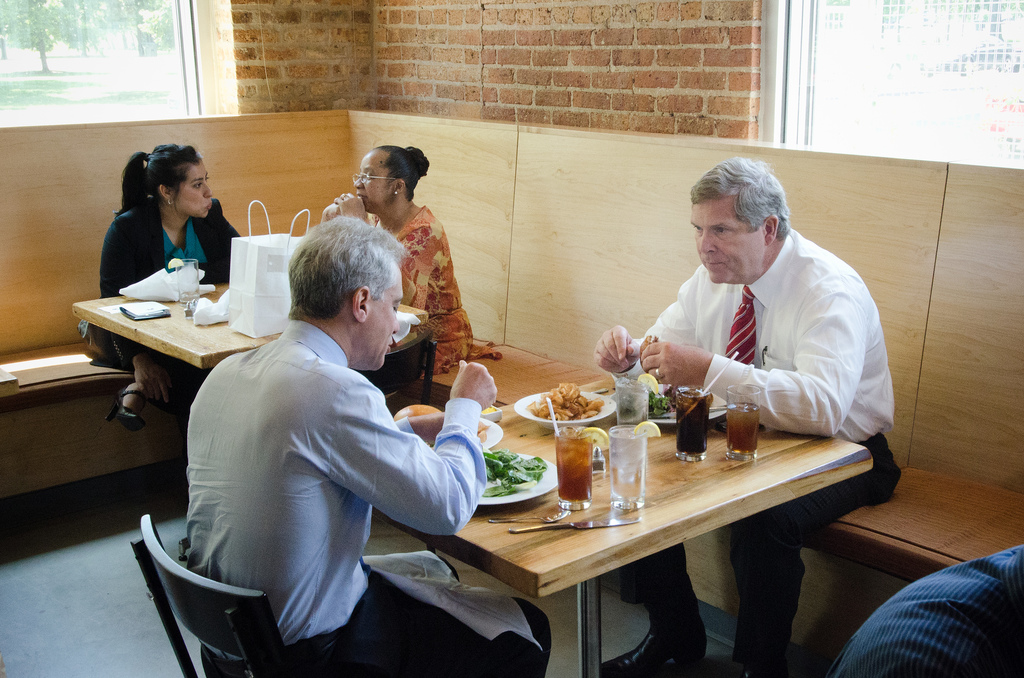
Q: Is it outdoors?
A: Yes, it is outdoors.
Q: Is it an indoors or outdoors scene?
A: It is outdoors.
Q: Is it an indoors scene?
A: No, it is outdoors.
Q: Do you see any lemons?
A: Yes, there is a lemon.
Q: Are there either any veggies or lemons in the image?
A: Yes, there is a lemon.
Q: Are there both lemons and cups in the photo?
A: Yes, there are both a lemon and a cup.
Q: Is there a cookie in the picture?
A: No, there are no cookies.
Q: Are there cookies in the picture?
A: No, there are no cookies.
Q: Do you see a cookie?
A: No, there are no cookies.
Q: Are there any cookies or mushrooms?
A: No, there are no cookies or mushrooms.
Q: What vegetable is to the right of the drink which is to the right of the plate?
A: The vegetable is a lemon.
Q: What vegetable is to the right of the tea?
A: The vegetable is a lemon.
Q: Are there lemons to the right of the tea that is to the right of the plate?
A: Yes, there is a lemon to the right of the tea.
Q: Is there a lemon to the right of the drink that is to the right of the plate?
A: Yes, there is a lemon to the right of the tea.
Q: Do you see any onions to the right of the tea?
A: No, there is a lemon to the right of the tea.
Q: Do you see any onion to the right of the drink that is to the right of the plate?
A: No, there is a lemon to the right of the tea.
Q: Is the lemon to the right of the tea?
A: Yes, the lemon is to the right of the tea.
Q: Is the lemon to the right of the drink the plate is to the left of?
A: Yes, the lemon is to the right of the tea.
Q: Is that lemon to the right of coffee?
A: No, the lemon is to the right of the tea.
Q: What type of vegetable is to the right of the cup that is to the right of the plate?
A: The vegetable is a lemon.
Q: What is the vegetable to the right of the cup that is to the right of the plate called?
A: The vegetable is a lemon.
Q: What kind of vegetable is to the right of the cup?
A: The vegetable is a lemon.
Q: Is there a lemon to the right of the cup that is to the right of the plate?
A: Yes, there is a lemon to the right of the cup.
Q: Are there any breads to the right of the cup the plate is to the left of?
A: No, there is a lemon to the right of the cup.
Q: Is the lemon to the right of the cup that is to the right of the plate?
A: Yes, the lemon is to the right of the cup.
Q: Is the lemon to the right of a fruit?
A: No, the lemon is to the right of the cup.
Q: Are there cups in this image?
A: Yes, there is a cup.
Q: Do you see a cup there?
A: Yes, there is a cup.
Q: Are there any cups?
A: Yes, there is a cup.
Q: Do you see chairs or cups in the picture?
A: Yes, there is a cup.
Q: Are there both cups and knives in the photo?
A: Yes, there are both a cup and a knife.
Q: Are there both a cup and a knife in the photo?
A: Yes, there are both a cup and a knife.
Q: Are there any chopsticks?
A: No, there are no chopsticks.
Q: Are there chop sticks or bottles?
A: No, there are no chop sticks or bottles.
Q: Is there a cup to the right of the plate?
A: Yes, there is a cup to the right of the plate.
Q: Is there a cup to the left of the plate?
A: No, the cup is to the right of the plate.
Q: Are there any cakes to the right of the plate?
A: No, there is a cup to the right of the plate.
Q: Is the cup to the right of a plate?
A: Yes, the cup is to the right of a plate.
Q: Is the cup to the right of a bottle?
A: No, the cup is to the right of a plate.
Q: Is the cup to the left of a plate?
A: No, the cup is to the right of a plate.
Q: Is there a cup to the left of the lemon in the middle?
A: Yes, there is a cup to the left of the lemon.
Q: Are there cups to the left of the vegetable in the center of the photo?
A: Yes, there is a cup to the left of the lemon.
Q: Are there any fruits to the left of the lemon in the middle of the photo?
A: No, there is a cup to the left of the lemon.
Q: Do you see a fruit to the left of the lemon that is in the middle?
A: No, there is a cup to the left of the lemon.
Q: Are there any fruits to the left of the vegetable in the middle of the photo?
A: No, there is a cup to the left of the lemon.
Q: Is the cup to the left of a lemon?
A: Yes, the cup is to the left of a lemon.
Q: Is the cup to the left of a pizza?
A: No, the cup is to the left of a lemon.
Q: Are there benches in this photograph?
A: Yes, there is a bench.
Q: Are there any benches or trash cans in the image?
A: Yes, there is a bench.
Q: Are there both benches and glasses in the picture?
A: Yes, there are both a bench and glasses.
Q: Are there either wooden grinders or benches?
A: Yes, there is a wood bench.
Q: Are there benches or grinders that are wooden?
A: Yes, the bench is wooden.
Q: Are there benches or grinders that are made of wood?
A: Yes, the bench is made of wood.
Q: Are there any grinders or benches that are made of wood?
A: Yes, the bench is made of wood.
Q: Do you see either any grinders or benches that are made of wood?
A: Yes, the bench is made of wood.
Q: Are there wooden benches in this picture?
A: Yes, there is a wood bench.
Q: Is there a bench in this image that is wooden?
A: Yes, there is a bench that is wooden.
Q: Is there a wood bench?
A: Yes, there is a bench that is made of wood.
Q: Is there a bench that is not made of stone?
A: Yes, there is a bench that is made of wood.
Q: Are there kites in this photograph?
A: No, there are no kites.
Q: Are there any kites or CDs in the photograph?
A: No, there are no kites or cds.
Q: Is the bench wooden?
A: Yes, the bench is wooden.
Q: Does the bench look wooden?
A: Yes, the bench is wooden.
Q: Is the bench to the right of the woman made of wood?
A: Yes, the bench is made of wood.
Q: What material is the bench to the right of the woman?
A: The bench is made of wood.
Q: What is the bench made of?
A: The bench is made of wood.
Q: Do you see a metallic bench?
A: No, there is a bench but it is wooden.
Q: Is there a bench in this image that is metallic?
A: No, there is a bench but it is wooden.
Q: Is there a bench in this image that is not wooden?
A: No, there is a bench but it is wooden.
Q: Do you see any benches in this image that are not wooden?
A: No, there is a bench but it is wooden.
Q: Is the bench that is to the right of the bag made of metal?
A: No, the bench is made of wood.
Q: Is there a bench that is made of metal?
A: No, there is a bench but it is made of wood.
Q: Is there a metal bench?
A: No, there is a bench but it is made of wood.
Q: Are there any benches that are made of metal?
A: No, there is a bench but it is made of wood.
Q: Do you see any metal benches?
A: No, there is a bench but it is made of wood.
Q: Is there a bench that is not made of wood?
A: No, there is a bench but it is made of wood.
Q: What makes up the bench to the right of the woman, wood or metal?
A: The bench is made of wood.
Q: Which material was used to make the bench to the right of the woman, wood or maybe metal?
A: The bench is made of wood.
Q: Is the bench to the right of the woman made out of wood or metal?
A: The bench is made of wood.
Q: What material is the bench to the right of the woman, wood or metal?
A: The bench is made of wood.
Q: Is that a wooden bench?
A: Yes, that is a wooden bench.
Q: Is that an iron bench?
A: No, that is a wooden bench.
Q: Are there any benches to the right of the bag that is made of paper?
A: Yes, there is a bench to the right of the bag.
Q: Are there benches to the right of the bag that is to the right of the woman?
A: Yes, there is a bench to the right of the bag.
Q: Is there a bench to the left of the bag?
A: No, the bench is to the right of the bag.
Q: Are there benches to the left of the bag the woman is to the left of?
A: No, the bench is to the right of the bag.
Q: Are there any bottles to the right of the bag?
A: No, there is a bench to the right of the bag.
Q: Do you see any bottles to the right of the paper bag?
A: No, there is a bench to the right of the bag.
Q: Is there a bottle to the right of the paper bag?
A: No, there is a bench to the right of the bag.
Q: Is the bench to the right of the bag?
A: Yes, the bench is to the right of the bag.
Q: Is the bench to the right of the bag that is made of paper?
A: Yes, the bench is to the right of the bag.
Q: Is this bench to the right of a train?
A: No, the bench is to the right of the bag.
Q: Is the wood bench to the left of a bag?
A: No, the bench is to the right of a bag.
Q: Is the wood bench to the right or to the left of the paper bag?
A: The bench is to the right of the bag.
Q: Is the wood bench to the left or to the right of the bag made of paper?
A: The bench is to the right of the bag.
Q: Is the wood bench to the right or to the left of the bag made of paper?
A: The bench is to the right of the bag.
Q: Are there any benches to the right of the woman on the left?
A: Yes, there is a bench to the right of the woman.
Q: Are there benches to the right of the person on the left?
A: Yes, there is a bench to the right of the woman.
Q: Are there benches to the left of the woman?
A: No, the bench is to the right of the woman.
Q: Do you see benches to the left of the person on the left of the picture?
A: No, the bench is to the right of the woman.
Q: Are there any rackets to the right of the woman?
A: No, there is a bench to the right of the woman.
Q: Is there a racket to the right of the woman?
A: No, there is a bench to the right of the woman.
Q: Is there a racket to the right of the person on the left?
A: No, there is a bench to the right of the woman.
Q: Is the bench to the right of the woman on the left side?
A: Yes, the bench is to the right of the woman.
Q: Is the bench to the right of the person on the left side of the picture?
A: Yes, the bench is to the right of the woman.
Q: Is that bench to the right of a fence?
A: No, the bench is to the right of the woman.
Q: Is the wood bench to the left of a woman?
A: No, the bench is to the right of a woman.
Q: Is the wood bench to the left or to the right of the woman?
A: The bench is to the right of the woman.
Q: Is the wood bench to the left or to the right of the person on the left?
A: The bench is to the right of the woman.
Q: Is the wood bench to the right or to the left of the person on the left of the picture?
A: The bench is to the right of the woman.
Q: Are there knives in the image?
A: Yes, there is a knife.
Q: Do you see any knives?
A: Yes, there is a knife.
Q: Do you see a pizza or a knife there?
A: Yes, there is a knife.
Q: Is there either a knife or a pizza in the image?
A: Yes, there is a knife.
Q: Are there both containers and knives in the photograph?
A: No, there is a knife but no containers.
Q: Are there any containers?
A: No, there are no containers.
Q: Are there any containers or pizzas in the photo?
A: No, there are no containers or pizzas.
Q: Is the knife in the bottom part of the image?
A: Yes, the knife is in the bottom of the image.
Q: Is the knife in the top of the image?
A: No, the knife is in the bottom of the image.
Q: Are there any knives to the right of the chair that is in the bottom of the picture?
A: Yes, there is a knife to the right of the chair.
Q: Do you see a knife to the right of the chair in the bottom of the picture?
A: Yes, there is a knife to the right of the chair.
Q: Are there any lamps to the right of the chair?
A: No, there is a knife to the right of the chair.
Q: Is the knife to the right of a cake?
A: No, the knife is to the right of the chair.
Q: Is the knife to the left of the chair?
A: No, the knife is to the right of the chair.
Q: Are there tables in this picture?
A: Yes, there is a table.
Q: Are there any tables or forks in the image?
A: Yes, there is a table.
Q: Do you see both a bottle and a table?
A: No, there is a table but no bottles.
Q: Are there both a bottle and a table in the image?
A: No, there is a table but no bottles.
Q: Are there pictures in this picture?
A: No, there are no pictures.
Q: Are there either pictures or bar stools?
A: No, there are no pictures or bar stools.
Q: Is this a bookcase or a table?
A: This is a table.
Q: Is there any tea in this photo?
A: Yes, there is tea.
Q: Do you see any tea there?
A: Yes, there is tea.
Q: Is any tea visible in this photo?
A: Yes, there is tea.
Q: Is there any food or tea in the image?
A: Yes, there is tea.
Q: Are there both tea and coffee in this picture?
A: No, there is tea but no coffee.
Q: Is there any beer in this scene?
A: No, there is no beer.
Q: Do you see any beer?
A: No, there is no beer.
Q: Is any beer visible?
A: No, there is no beer.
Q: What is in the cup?
A: The tea is in the cup.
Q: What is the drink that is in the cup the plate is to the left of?
A: The drink is tea.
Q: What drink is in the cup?
A: The drink is tea.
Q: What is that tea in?
A: The tea is in the cup.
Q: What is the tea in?
A: The tea is in the cup.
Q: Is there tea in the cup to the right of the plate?
A: Yes, there is tea in the cup.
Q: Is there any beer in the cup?
A: No, there is tea in the cup.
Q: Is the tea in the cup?
A: Yes, the tea is in the cup.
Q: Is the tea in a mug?
A: No, the tea is in the cup.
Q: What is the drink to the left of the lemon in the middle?
A: The drink is tea.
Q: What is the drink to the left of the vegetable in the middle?
A: The drink is tea.